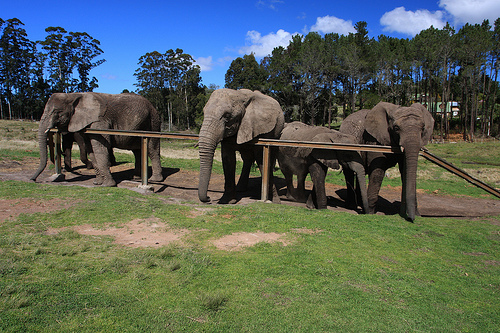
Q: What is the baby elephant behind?
A: Rail.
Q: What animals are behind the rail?
A: Elephants.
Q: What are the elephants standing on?
A: Dirt.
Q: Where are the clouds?
A: In the sky.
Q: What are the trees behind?
A: Elephants.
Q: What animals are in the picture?
A: Elephants.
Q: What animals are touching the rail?
A: Elephants.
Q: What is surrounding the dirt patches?
A: Grass.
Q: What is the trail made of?
A: Dirt.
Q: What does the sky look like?
A: Bright blue.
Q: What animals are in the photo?
A: Elephants.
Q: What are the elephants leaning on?
A: A rail.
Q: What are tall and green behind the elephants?
A: The trees.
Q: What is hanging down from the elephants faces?
A: Their trunks.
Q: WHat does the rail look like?
A: Old and rusty.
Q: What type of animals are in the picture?
A: Elephants.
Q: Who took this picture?
A: Tourist.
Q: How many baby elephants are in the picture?
A: One.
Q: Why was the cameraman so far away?
A: Safety.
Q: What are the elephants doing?
A: Eating.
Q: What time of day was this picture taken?
A: Afternoon.